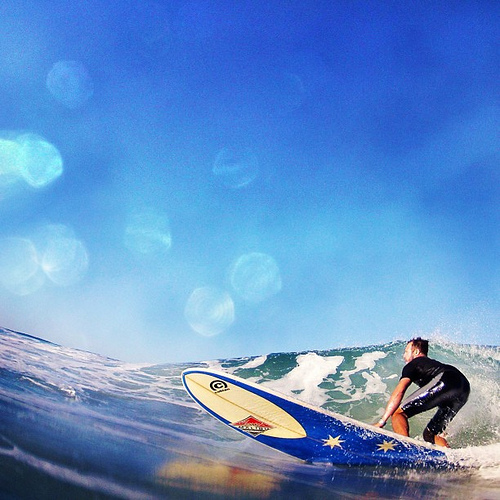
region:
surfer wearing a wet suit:
[402, 306, 492, 465]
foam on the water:
[231, 324, 356, 402]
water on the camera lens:
[34, 147, 272, 341]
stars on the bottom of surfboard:
[325, 419, 426, 467]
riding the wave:
[289, 291, 496, 449]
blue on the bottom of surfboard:
[297, 410, 429, 490]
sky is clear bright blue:
[206, 22, 461, 144]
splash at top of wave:
[433, 317, 499, 375]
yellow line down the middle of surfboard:
[183, 365, 384, 482]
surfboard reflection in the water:
[137, 429, 287, 497]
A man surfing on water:
[165, 326, 461, 466]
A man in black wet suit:
[386, 340, 471, 422]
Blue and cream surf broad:
[188, 406, 435, 484]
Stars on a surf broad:
[301, 426, 365, 455]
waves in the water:
[18, 354, 179, 450]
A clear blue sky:
[68, 118, 473, 296]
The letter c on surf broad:
[193, 376, 228, 401]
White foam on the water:
[273, 345, 360, 380]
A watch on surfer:
[368, 416, 393, 428]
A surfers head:
[392, 332, 432, 372]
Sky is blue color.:
[165, 54, 387, 119]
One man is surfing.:
[178, 323, 484, 468]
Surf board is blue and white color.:
[200, 374, 375, 476]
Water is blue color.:
[38, 373, 105, 480]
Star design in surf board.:
[307, 408, 426, 463]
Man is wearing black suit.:
[379, 357, 447, 460]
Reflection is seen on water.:
[146, 446, 291, 496]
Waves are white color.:
[69, 343, 209, 382]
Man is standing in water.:
[341, 378, 485, 484]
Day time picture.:
[28, 227, 485, 454]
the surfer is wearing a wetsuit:
[379, 340, 471, 451]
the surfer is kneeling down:
[376, 336, 469, 453]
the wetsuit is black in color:
[400, 356, 474, 441]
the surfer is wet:
[373, 338, 477, 446]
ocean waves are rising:
[6, 326, 495, 472]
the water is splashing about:
[358, 318, 493, 367]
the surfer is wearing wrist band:
[379, 416, 387, 426]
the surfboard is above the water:
[181, 363, 451, 472]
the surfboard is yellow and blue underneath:
[184, 366, 446, 473]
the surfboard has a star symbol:
[321, 429, 343, 451]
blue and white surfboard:
[174, 345, 491, 499]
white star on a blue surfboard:
[312, 424, 362, 469]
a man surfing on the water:
[341, 303, 479, 474]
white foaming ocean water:
[252, 337, 357, 408]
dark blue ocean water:
[35, 366, 138, 448]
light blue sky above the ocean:
[0, 112, 246, 291]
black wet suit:
[382, 347, 479, 468]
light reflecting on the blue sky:
[19, 181, 193, 304]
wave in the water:
[323, 312, 489, 405]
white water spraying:
[422, 302, 492, 359]